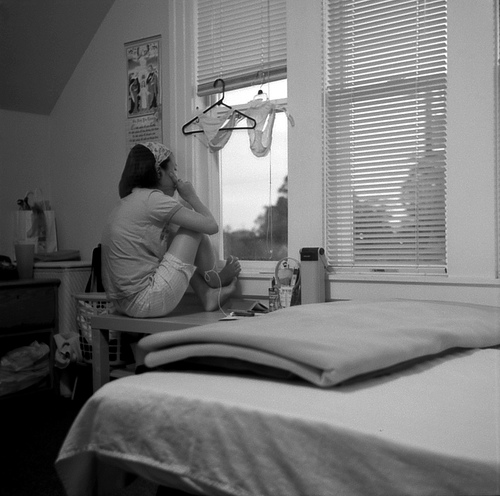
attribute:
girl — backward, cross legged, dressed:
[108, 136, 245, 321]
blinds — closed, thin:
[325, 6, 455, 280]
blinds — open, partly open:
[193, 3, 297, 86]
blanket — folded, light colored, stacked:
[134, 297, 498, 384]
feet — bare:
[204, 255, 248, 315]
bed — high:
[61, 327, 498, 490]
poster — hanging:
[117, 33, 182, 173]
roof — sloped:
[6, 3, 127, 126]